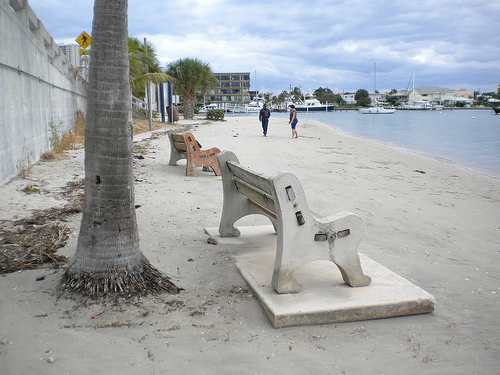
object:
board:
[74, 30, 90, 50]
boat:
[359, 107, 396, 114]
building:
[173, 72, 251, 107]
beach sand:
[327, 143, 417, 196]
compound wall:
[1, 1, 87, 187]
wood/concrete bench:
[226, 161, 351, 241]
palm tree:
[60, 0, 181, 295]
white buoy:
[472, 117, 475, 119]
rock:
[44, 350, 54, 362]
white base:
[204, 226, 436, 328]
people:
[259, 103, 298, 138]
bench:
[167, 129, 221, 177]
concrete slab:
[204, 219, 436, 328]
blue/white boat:
[293, 99, 338, 111]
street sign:
[73, 30, 90, 49]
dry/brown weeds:
[40, 108, 89, 161]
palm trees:
[163, 57, 219, 119]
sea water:
[228, 109, 499, 173]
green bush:
[207, 108, 225, 121]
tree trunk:
[74, 0, 150, 265]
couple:
[258, 104, 298, 139]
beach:
[0, 116, 499, 373]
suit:
[289, 109, 299, 129]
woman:
[288, 105, 299, 139]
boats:
[487, 98, 500, 115]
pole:
[411, 63, 414, 88]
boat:
[405, 98, 433, 107]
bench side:
[268, 172, 370, 293]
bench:
[214, 150, 372, 293]